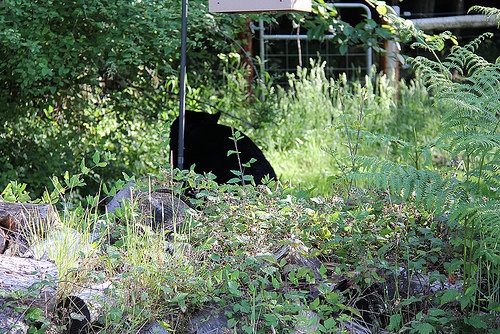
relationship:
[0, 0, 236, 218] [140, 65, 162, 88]
leaf in trees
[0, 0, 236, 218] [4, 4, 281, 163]
leaf in trees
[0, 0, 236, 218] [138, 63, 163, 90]
leaf in tree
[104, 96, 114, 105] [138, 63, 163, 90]
leaf in tree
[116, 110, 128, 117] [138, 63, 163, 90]
leaf in tree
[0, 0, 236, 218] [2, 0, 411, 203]
leaf in tree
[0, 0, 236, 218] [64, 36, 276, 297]
leaf in trees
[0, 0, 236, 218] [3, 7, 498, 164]
leaf in trees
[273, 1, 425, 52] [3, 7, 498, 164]
leaves in trees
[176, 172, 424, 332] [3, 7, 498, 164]
leaves in trees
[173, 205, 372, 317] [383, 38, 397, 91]
leaves in tree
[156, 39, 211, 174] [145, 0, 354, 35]
pole supporting bird house